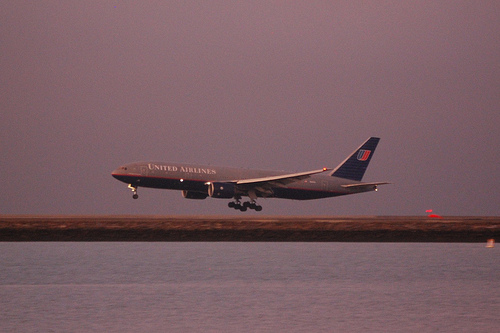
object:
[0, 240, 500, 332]
water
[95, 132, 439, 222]
airplane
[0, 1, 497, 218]
sky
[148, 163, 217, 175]
font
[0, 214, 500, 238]
ground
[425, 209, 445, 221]
windsock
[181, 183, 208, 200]
engine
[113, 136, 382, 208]
plane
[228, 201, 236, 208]
round wheels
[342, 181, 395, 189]
wings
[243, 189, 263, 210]
landing gear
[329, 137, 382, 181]
blue symbol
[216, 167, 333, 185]
wing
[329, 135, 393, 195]
tail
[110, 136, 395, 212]
aircraft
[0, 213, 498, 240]
land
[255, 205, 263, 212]
gear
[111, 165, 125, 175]
nose cone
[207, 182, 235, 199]
engine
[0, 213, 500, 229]
airstrip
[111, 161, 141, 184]
head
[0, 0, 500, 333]
air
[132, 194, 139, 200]
wheels